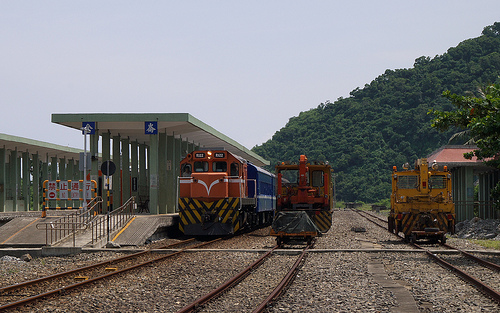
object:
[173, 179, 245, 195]
white lines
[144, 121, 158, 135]
pictures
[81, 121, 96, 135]
sign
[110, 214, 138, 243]
yellow line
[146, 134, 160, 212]
beam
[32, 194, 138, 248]
handrails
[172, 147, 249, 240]
train engine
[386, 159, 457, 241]
vehicle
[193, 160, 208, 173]
window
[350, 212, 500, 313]
track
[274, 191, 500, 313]
pebbles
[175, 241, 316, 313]
track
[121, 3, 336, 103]
clouds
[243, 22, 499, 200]
trees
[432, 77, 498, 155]
leaves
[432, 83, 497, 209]
tree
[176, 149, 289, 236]
train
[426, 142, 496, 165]
roof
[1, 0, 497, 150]
clouds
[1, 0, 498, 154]
sky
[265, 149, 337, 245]
trains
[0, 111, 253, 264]
train platform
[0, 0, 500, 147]
blue sky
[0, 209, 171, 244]
platform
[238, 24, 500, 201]
hillside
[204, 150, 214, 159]
light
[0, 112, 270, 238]
transit stop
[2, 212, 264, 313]
track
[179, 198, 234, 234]
bumper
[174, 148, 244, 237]
front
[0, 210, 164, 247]
ramp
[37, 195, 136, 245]
railling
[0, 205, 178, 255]
pavement